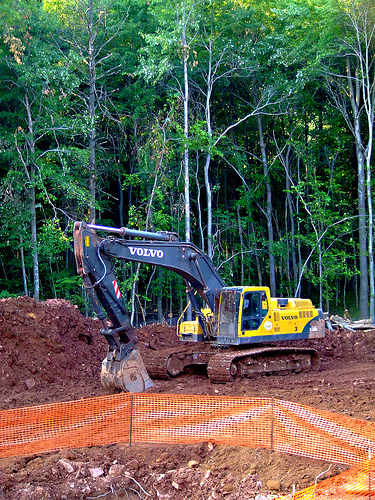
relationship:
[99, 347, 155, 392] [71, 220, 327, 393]
bucket attached to tractor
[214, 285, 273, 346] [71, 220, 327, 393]
cab built onto tractor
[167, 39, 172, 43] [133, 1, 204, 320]
leaf growing on tree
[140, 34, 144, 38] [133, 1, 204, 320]
leaf growing on tree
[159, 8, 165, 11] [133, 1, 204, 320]
leaf growing on tree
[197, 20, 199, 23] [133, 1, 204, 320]
leaf growing on tree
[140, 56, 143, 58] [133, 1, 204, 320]
leaf growing on tree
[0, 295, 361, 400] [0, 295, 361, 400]
dirt pile lying in dirt pile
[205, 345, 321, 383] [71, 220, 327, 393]
tread steadying tractor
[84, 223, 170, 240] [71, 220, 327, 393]
hydraulic mounted on tractor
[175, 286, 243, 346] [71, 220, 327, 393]
front belonging to tractor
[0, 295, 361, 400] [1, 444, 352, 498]
dirt pile dug out of hole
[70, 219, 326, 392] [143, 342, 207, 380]
backhoe rolling on track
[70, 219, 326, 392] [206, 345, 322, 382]
backhoe rolling on track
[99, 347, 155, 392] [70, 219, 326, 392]
bucket attached to backhoe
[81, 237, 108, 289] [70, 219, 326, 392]
hydraulic hose attached to backhoe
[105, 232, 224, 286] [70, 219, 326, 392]
hydraulic hose attached to backhoe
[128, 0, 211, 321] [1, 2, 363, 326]
tree forming stand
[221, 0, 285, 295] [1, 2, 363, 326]
tree forming stand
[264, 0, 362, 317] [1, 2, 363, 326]
tree forming stand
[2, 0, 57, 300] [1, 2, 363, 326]
tree forming stand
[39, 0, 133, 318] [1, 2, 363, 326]
tree forming stand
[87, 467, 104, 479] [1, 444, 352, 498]
rock lying in hole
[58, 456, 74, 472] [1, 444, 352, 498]
rock lying in hole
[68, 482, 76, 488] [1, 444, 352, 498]
rock lying in hole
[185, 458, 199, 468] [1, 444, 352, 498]
rock lying in hole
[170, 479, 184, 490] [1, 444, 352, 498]
rock lying in hole